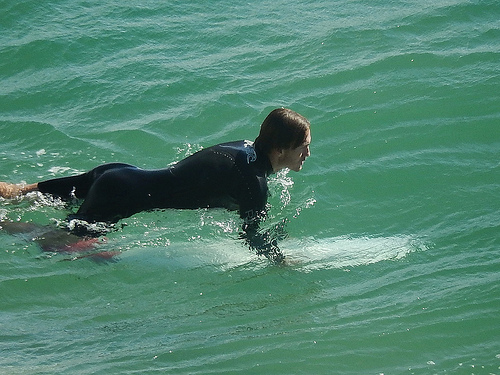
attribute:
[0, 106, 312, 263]
man — surfing, swimming, wet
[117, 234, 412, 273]
surfboard — submerged, white, red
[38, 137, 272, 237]
wetsuit — black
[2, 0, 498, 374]
ocean — blue, green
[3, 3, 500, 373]
water — clean, green, blue, splashing, white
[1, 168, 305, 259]
waves — green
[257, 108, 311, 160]
hair — brown, wet